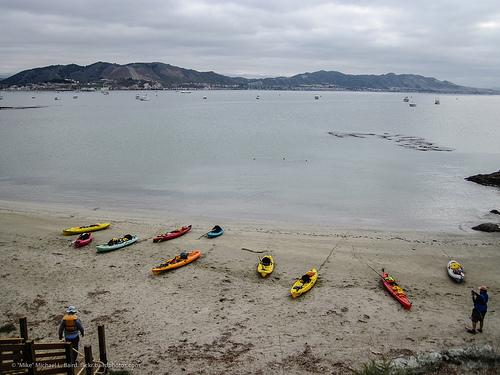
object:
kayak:
[288, 267, 324, 300]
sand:
[2, 203, 500, 374]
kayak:
[379, 266, 414, 313]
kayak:
[151, 223, 193, 244]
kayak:
[150, 249, 203, 275]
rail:
[2, 315, 110, 374]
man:
[58, 304, 86, 361]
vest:
[61, 313, 80, 332]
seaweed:
[83, 283, 118, 300]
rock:
[471, 221, 499, 232]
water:
[2, 89, 500, 233]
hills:
[0, 59, 233, 87]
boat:
[409, 101, 419, 109]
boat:
[314, 93, 321, 101]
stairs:
[84, 326, 107, 375]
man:
[467, 285, 490, 336]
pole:
[96, 329, 109, 364]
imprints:
[217, 294, 238, 303]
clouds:
[0, 1, 499, 78]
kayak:
[206, 222, 225, 239]